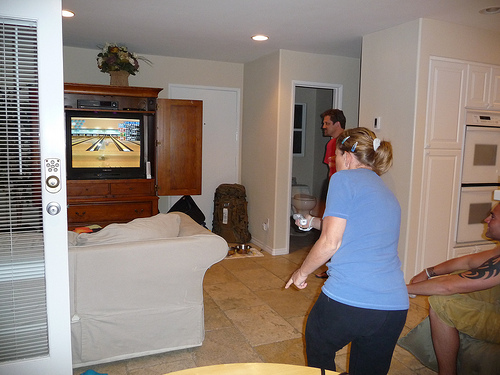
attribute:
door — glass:
[1, 1, 78, 373]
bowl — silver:
[234, 242, 252, 258]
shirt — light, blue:
[326, 166, 406, 301]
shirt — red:
[323, 132, 347, 175]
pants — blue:
[303, 287, 413, 373]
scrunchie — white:
[370, 135, 382, 152]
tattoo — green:
[457, 253, 499, 285]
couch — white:
[0, 205, 232, 367]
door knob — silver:
[46, 201, 61, 215]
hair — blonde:
[338, 131, 397, 173]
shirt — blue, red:
[314, 165, 414, 311]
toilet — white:
[292, 184, 314, 228]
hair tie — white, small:
[371, 136, 381, 152]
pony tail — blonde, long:
[360, 134, 395, 174]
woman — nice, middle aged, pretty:
[282, 127, 405, 370]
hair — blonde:
[326, 122, 398, 171]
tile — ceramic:
[76, 247, 341, 374]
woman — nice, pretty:
[218, 100, 431, 358]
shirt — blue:
[240, 182, 448, 321]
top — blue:
[313, 164, 418, 316]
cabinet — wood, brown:
[4, 72, 214, 236]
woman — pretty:
[288, 127, 438, 369]